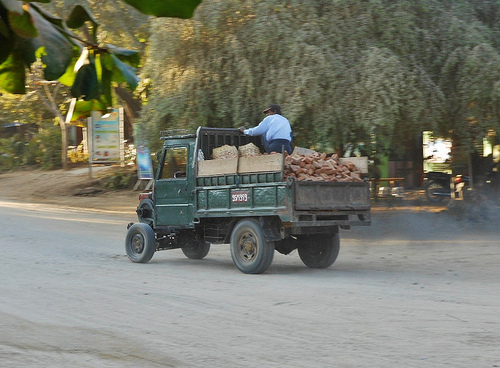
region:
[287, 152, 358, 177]
Wood on the truck.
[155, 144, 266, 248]
The truck is green.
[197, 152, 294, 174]
The board is brown.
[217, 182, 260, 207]
Number on the truck.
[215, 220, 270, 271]
The wheel is black.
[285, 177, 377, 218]
The gate is black.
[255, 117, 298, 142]
The man has a blue shirt.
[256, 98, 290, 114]
The man is wearing a hat.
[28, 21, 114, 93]
The leaves are green.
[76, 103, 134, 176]
Sign in a driveway.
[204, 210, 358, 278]
back wheels of the vehicle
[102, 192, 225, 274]
front wheels of the vehicle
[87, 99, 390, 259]
the vehicle is green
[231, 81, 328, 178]
man is in the bed of the vehicle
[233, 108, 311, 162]
man is wearing a light blue shirt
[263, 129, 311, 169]
man is wearing dark blue pants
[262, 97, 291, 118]
man is wearing dark sunglasses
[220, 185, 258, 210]
writing on the vehicle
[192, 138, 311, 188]
wooden barricade on the vehicle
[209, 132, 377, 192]
objects in the bed of the vehicle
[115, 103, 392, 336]
a green truck on the road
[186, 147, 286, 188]
boards along the edge of the truck bed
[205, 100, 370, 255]
man in the back of the truck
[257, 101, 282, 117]
man wearing a baseball cap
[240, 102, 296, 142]
man wearing a long-sleeved sweater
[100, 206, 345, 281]
the front wheels of the truck are lower than the back wheels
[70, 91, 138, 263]
sign beside the road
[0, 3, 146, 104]
large green leaves on a branch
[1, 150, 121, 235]
dirt pathway leading from the road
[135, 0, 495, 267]
large tree behind truck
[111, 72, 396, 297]
green truck with man in it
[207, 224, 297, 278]
black tires on truck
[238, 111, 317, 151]
man in back of truck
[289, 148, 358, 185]
stuff in back of truck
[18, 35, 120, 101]
leaves of a tree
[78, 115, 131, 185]
sign with writing on it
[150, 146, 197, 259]
door of truck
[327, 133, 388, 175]
vehicle behind trees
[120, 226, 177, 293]
front tire of truck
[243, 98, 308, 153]
man wearing a hat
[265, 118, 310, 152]
blue shirt on man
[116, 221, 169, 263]
black tires on vehicle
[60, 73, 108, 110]
green leaves on tree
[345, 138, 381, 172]
vehicle next to tree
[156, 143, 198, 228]
green door on vehicle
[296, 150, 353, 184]
stuff in the back of the truck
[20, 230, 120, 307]
black road with vehicle on it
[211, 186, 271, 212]
writing on side of truck